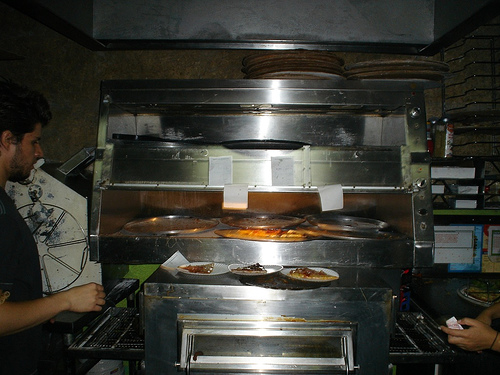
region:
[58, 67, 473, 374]
Large metal pizza oven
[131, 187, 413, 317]
Pizzas cooking inside oven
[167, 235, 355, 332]
Three small round white plates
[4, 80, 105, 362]
Man with dark brown hair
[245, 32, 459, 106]
Stacks of pizza plates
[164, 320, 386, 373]
Small clear door for pizzaas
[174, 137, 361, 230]
Tickets taped on the pizza oven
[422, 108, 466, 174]
Jars of spices on the shelves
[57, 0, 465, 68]
Top silver part of roof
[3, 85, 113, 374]
Man looking at pizzas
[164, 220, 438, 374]
FOOD ON A PLATE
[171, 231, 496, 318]
food on plates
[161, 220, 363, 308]
pizzas on plates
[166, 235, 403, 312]
slices of pizzas on plates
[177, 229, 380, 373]
pizzas on a white plate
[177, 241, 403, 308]
slices of pizzas on white plates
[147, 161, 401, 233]
pizzas in an oven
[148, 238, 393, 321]
plates with pizzas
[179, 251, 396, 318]
plates with slices of pizza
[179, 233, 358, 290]
white plates with pizzas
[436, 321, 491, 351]
a persons hand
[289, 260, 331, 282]
food on the plate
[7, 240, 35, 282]
man is wearing a black shirt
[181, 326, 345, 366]
an oven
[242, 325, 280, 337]
reflection of light on the oven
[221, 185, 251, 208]
a white paper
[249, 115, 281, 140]
reflection of light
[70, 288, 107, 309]
the mans hand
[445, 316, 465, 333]
paper in hand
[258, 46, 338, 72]
pizza pans stacked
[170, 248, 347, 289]
slices of pizza on plates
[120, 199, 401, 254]
4 pizza pans, one with a pizza on it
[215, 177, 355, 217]
order tags hanging from work station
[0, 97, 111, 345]
bearded man with black shirt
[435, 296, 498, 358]
hand holding something white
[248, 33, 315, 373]
glare running down center of steel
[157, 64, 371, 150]
large rounded metal piece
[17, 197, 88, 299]
metal pizza slicer hanging from wall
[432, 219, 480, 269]
piece of paper hanging from wall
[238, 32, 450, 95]
stacks of round objects on high shelf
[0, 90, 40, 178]
man has dark hair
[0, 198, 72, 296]
man has black shirt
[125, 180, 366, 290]
pizzas rotating in oven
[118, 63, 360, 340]
oven has metal exterior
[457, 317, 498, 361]
person wears black bracelet on right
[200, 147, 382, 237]
white tickets on oven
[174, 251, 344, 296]
slices of pizza on white plates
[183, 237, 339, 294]
single slices below whole pies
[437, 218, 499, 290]
blue box on right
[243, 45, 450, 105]
used pizza stones atop oven